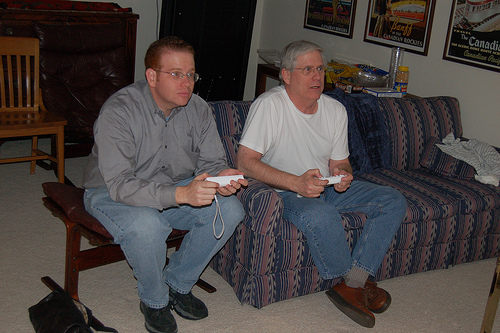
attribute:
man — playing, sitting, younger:
[83, 35, 249, 332]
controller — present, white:
[206, 173, 244, 189]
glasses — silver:
[154, 68, 201, 79]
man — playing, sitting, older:
[236, 40, 406, 326]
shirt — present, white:
[237, 85, 349, 191]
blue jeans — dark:
[275, 179, 407, 278]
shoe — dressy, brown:
[324, 276, 375, 327]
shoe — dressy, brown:
[362, 280, 392, 313]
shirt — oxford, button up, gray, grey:
[83, 81, 227, 209]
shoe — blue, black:
[138, 297, 177, 332]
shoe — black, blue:
[168, 279, 208, 319]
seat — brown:
[41, 179, 217, 318]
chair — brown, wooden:
[0, 35, 67, 183]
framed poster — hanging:
[303, 0, 357, 39]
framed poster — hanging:
[361, 0, 438, 57]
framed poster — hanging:
[442, 0, 500, 73]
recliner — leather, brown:
[32, 22, 125, 187]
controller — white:
[317, 173, 345, 184]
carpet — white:
[0, 138, 499, 332]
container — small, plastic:
[393, 66, 409, 95]